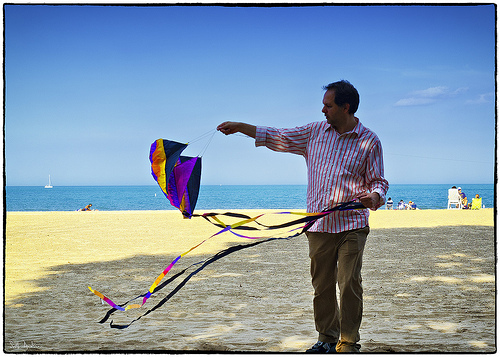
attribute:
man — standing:
[260, 70, 389, 316]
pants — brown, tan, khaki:
[301, 229, 364, 342]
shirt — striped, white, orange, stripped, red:
[287, 132, 371, 222]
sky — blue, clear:
[48, 18, 456, 96]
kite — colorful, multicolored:
[143, 142, 232, 230]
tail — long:
[201, 205, 302, 246]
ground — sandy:
[40, 217, 483, 283]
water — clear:
[35, 183, 153, 211]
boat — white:
[34, 166, 63, 192]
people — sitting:
[393, 194, 486, 224]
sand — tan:
[79, 249, 487, 336]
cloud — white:
[397, 87, 479, 115]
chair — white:
[442, 188, 458, 207]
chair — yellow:
[471, 198, 485, 209]